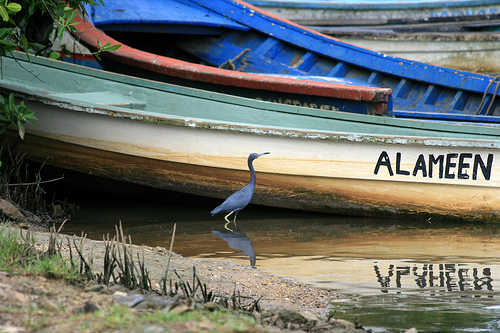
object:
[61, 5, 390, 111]
trim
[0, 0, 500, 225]
boats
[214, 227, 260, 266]
reflection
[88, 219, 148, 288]
plants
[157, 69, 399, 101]
edge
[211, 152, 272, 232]
bird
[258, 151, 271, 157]
beak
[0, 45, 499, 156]
trim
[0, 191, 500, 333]
ground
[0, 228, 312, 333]
dirt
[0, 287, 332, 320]
shore line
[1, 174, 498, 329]
water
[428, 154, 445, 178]
black m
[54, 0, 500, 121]
canoe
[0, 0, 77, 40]
leaves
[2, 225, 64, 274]
grass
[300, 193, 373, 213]
algae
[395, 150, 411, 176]
word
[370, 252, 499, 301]
reflection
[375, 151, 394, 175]
letters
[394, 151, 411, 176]
l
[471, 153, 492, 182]
letter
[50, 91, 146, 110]
seat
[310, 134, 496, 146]
paint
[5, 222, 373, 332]
shore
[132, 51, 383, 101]
paint